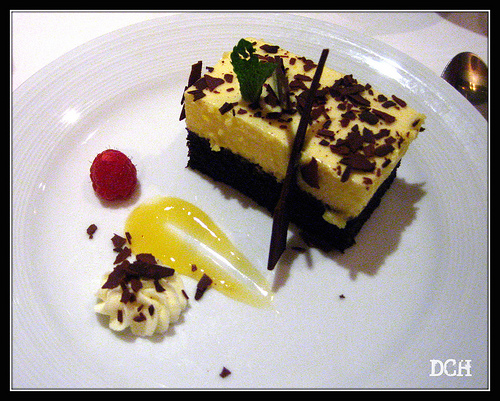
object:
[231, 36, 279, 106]
garnish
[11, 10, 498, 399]
plate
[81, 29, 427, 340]
dessert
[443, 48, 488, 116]
spoon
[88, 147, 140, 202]
raspberry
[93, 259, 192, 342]
cream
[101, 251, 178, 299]
shavings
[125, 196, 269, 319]
gel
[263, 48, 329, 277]
shaving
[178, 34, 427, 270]
cake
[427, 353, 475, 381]
dch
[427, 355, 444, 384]
d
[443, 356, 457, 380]
c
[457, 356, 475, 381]
h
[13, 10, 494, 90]
table